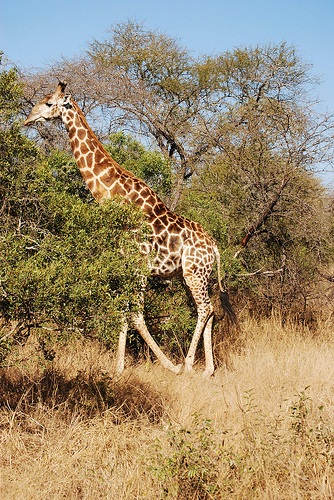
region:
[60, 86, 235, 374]
brown giraffe on grass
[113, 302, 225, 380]
giraffe has white legs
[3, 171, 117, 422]
green tree near giraffe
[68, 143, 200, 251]
brown and white spots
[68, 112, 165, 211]
giraffe has brown mane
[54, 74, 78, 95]
brown and black ossicles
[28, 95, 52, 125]
giraffe has brown nose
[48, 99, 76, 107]
giraffe has white ears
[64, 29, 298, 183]
tall and thin tree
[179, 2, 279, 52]
blue and clear sky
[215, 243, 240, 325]
the tail of a giraffe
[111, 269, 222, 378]
a giraffe's long legs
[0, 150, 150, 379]
a thorny green bush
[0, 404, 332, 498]
lots of dying grass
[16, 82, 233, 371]
a giraffe munching on leaves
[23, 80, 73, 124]
a giraffe head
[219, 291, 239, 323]
the black part of a giraffe tail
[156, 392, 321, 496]
a few green plants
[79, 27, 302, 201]
tall leafless trees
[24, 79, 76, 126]
a giraffe eating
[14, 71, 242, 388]
a giraffe grazing the top leaves of a tree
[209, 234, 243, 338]
giraffe has a long thin tail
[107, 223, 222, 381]
giraffe's front legs are longer than its back legs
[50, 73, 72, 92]
giraffe has short tufted horns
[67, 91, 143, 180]
giraffe has a short brown mane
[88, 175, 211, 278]
giraffe's spots fit together like an interlocking mosaic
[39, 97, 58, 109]
giraffe has dark gentle eyes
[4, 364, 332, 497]
dry grasses around the giraffe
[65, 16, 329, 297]
tall tree behind the giraffe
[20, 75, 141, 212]
giraffe's long neck enables it to graze treetops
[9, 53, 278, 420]
tall zebra amongst the trees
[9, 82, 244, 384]
brown giraffe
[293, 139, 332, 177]
white clouds in blue sky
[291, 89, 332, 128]
white clouds in blue sky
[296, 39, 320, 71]
white clouds in blue sky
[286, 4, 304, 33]
white clouds in blue sky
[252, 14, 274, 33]
white clouds in blue sky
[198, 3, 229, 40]
white clouds in blue sky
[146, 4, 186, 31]
white clouds in blue sky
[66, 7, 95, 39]
white clouds in blue sky